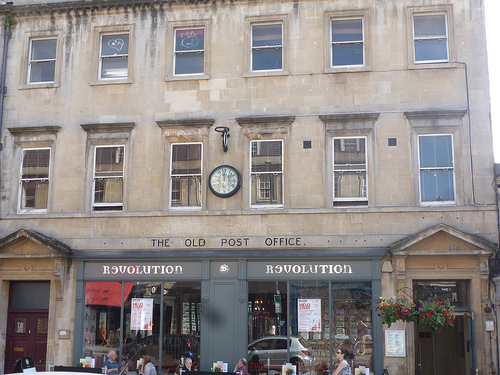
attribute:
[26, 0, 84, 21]
roof — edge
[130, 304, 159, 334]
graphic — part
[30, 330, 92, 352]
plant — part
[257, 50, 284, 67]
glass — part, frosted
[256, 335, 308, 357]
car — driving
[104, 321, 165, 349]
door — part, brown, maroon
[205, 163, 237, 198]
clock — part, big, black, white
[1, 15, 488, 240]
building — post office, cream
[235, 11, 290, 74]
window — open, white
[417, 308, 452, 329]
flowers — hanging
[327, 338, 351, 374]
woman — walking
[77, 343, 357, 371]
people — some, sitting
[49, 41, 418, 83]
windows — some, closed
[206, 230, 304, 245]
lettering — black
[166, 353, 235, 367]
man — sitting